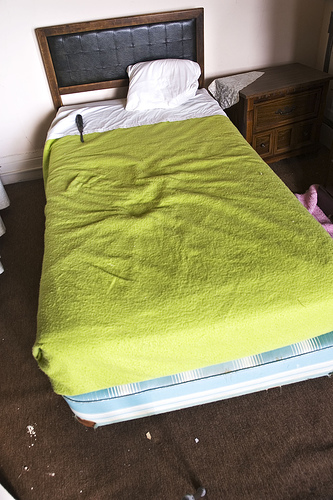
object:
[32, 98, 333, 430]
bed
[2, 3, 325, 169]
wall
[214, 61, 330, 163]
cabinet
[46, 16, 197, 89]
cushion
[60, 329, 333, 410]
matress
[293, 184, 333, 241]
clothing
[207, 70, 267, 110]
clothing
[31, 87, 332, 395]
bed spread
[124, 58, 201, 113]
bed pillow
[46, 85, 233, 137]
sheet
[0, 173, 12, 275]
curtains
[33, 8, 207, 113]
head board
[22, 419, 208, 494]
debris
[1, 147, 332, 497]
carpet